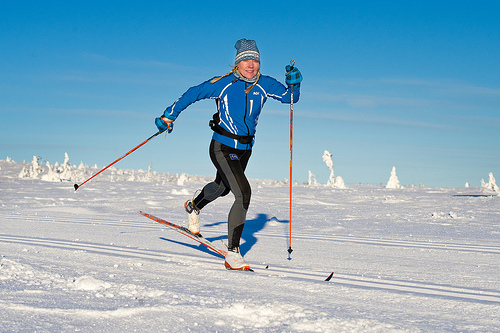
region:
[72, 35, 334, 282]
the white woman skiing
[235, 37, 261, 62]
the beanie on the woman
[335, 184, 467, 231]
the snow on the ground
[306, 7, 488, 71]
the clear blue sky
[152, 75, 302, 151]
the blue and white ski jacket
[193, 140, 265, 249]
the black and gray pants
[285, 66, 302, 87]
the blue and black ski globes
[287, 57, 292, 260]
the red ski pole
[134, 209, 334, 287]
the two ski shoes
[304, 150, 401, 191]
the snow above the ground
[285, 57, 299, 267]
the ski brake is red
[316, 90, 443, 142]
there is a white cloud in the sky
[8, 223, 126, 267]
tracks in the snow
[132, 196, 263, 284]
the skis are red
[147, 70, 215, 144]
her arm is extended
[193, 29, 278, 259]
the woman is on skis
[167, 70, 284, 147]
the woman wears a blue and white jacket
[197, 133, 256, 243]
the woman wears black and gray tights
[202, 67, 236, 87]
the woman has blonde braided hair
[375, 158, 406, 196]
the tree is small, gar and covered in snow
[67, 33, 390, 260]
skier wearing a blue jacket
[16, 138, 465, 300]
white field of snow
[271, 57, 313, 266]
red ski pole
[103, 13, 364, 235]
skier skiing down the slope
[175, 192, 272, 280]
a pair of ski shoes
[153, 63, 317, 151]
warm red ski jacket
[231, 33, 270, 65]
blue warm hat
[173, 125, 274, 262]
black pants for warmth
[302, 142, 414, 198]
white snow sculptures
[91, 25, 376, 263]
skier wearing blue jacket and black pants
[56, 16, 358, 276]
woman cross country skiing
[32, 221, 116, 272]
tracks made by skis in the snow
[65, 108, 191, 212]
woman holding red ski poles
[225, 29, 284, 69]
woman wearing blue hat with white stripes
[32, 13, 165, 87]
bright clear blue sky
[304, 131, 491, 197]
snow covered trees in the background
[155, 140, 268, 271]
woman wearing grey and black ski pants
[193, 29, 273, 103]
woman with blonde hair in braided pig tails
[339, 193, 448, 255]
ground covered with snow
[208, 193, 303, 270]
shadow of woman on snow behind her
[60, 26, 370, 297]
woman skiing in the snow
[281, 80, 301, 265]
long, orange ski pole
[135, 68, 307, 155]
blue and white jacket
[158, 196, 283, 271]
shadow of the woman and her skis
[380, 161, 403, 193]
small, white triangle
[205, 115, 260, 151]
black strap wrapped around the waist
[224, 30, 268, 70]
hat on the head right above the eyes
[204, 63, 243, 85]
blonde hair poking out of the hat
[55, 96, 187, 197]
ski pole extended backwards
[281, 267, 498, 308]
ski tracks in the snow